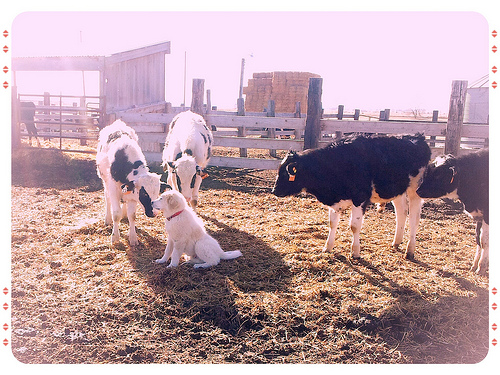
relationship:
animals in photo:
[92, 105, 486, 272] [43, 27, 473, 340]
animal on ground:
[150, 189, 243, 268] [90, 212, 329, 343]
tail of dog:
[218, 244, 245, 266] [155, 179, 242, 272]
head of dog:
[141, 180, 190, 222] [156, 183, 236, 291]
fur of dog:
[186, 223, 206, 246] [148, 188, 248, 273]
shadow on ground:
[374, 274, 488, 374] [16, 143, 472, 347]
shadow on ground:
[197, 199, 287, 294] [16, 143, 472, 347]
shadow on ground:
[128, 228, 243, 336] [16, 143, 472, 347]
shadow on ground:
[11, 141, 98, 194] [16, 143, 472, 347]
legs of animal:
[322, 199, 422, 266] [271, 132, 432, 260]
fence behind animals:
[106, 76, 486, 196] [89, 98, 429, 288]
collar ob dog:
[165, 210, 185, 222] [144, 187, 253, 277]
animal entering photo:
[415, 148, 488, 276] [43, 27, 473, 340]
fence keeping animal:
[106, 76, 486, 196] [271, 132, 432, 260]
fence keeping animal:
[106, 76, 486, 196] [161, 109, 213, 210]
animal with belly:
[271, 132, 432, 260] [368, 188, 406, 209]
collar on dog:
[165, 210, 184, 221] [139, 184, 248, 271]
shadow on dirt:
[128, 228, 244, 331] [316, 276, 475, 352]